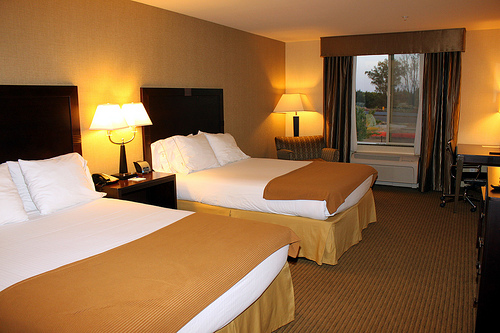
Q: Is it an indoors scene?
A: Yes, it is indoors.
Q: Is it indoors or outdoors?
A: It is indoors.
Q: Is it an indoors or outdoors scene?
A: It is indoors.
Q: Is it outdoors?
A: No, it is indoors.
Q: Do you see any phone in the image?
A: Yes, there is a phone.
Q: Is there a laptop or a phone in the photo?
A: Yes, there is a phone.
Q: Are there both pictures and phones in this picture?
A: No, there is a phone but no pictures.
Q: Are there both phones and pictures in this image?
A: No, there is a phone but no pictures.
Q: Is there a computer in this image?
A: No, there are no computers.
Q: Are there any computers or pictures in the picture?
A: No, there are no computers or pictures.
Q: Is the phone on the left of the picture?
A: Yes, the phone is on the left of the image.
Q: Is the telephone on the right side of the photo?
A: No, the telephone is on the left of the image.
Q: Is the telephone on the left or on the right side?
A: The telephone is on the left of the image.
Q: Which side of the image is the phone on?
A: The phone is on the left of the image.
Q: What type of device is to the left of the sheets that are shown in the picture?
A: The device is a phone.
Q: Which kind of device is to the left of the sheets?
A: The device is a phone.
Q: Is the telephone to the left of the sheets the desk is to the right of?
A: Yes, the telephone is to the left of the sheets.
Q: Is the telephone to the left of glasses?
A: No, the telephone is to the left of the sheets.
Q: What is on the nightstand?
A: The phone is on the nightstand.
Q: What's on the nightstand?
A: The phone is on the nightstand.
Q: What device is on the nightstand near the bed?
A: The device is a phone.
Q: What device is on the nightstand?
A: The device is a phone.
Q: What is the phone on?
A: The phone is on the nightstand.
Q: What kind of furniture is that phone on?
A: The phone is on the nightstand.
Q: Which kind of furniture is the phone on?
A: The phone is on the nightstand.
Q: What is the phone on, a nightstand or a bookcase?
A: The phone is on a nightstand.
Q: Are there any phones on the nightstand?
A: Yes, there is a phone on the nightstand.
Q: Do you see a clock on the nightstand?
A: No, there is a phone on the nightstand.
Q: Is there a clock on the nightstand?
A: No, there is a phone on the nightstand.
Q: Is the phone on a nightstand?
A: Yes, the phone is on a nightstand.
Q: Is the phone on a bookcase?
A: No, the phone is on a nightstand.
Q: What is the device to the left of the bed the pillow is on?
A: The device is a phone.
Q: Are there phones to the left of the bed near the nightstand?
A: Yes, there is a phone to the left of the bed.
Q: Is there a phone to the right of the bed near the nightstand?
A: No, the phone is to the left of the bed.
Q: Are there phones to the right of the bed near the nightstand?
A: No, the phone is to the left of the bed.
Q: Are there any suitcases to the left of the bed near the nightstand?
A: No, there is a phone to the left of the bed.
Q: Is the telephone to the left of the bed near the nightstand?
A: Yes, the telephone is to the left of the bed.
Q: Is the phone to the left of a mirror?
A: No, the phone is to the left of the bed.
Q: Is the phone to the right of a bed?
A: No, the phone is to the left of a bed.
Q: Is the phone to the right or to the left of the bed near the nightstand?
A: The phone is to the left of the bed.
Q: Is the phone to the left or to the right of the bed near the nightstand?
A: The phone is to the left of the bed.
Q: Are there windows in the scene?
A: Yes, there is a window.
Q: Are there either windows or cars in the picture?
A: Yes, there is a window.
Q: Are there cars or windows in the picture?
A: Yes, there is a window.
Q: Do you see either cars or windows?
A: Yes, there is a window.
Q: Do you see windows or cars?
A: Yes, there is a window.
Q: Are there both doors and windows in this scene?
A: No, there is a window but no doors.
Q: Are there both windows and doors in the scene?
A: No, there is a window but no doors.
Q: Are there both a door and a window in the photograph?
A: No, there is a window but no doors.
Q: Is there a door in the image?
A: No, there are no doors.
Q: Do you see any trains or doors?
A: No, there are no doors or trains.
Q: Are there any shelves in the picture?
A: No, there are no shelves.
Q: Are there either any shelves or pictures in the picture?
A: No, there are no shelves or pictures.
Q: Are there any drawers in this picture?
A: No, there are no drawers.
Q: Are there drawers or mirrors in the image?
A: No, there are no drawers or mirrors.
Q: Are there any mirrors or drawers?
A: No, there are no drawers or mirrors.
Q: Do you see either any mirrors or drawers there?
A: No, there are no drawers or mirrors.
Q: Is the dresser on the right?
A: Yes, the dresser is on the right of the image.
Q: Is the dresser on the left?
A: No, the dresser is on the right of the image.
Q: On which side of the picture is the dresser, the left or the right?
A: The dresser is on the right of the image.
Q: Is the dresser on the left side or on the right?
A: The dresser is on the right of the image.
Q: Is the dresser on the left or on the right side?
A: The dresser is on the right of the image.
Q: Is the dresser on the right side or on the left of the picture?
A: The dresser is on the right of the image.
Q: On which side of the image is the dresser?
A: The dresser is on the right of the image.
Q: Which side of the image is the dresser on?
A: The dresser is on the right of the image.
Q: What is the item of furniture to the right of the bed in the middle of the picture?
A: The piece of furniture is a dresser.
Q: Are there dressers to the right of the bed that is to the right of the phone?
A: Yes, there is a dresser to the right of the bed.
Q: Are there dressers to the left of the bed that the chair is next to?
A: No, the dresser is to the right of the bed.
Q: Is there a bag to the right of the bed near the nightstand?
A: No, there is a dresser to the right of the bed.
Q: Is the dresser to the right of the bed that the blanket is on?
A: Yes, the dresser is to the right of the bed.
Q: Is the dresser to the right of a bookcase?
A: No, the dresser is to the right of the bed.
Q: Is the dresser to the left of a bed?
A: No, the dresser is to the right of a bed.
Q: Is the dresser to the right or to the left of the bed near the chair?
A: The dresser is to the right of the bed.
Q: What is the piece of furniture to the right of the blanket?
A: The piece of furniture is a dresser.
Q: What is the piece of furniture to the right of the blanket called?
A: The piece of furniture is a dresser.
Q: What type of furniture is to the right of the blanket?
A: The piece of furniture is a dresser.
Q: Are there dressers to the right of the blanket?
A: Yes, there is a dresser to the right of the blanket.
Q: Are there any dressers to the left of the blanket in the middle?
A: No, the dresser is to the right of the blanket.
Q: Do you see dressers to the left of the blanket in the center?
A: No, the dresser is to the right of the blanket.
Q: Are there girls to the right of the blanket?
A: No, there is a dresser to the right of the blanket.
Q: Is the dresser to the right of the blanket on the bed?
A: Yes, the dresser is to the right of the blanket.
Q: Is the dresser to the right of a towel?
A: No, the dresser is to the right of the blanket.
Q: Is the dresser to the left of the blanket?
A: No, the dresser is to the right of the blanket.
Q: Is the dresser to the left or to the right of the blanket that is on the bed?
A: The dresser is to the right of the blanket.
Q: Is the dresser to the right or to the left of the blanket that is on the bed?
A: The dresser is to the right of the blanket.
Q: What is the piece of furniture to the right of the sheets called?
A: The piece of furniture is a dresser.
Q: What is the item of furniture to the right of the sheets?
A: The piece of furniture is a dresser.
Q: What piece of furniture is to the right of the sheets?
A: The piece of furniture is a dresser.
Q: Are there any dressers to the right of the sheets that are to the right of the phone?
A: Yes, there is a dresser to the right of the sheets.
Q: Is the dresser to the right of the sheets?
A: Yes, the dresser is to the right of the sheets.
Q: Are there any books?
A: No, there are no books.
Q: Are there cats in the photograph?
A: No, there are no cats.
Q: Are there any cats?
A: No, there are no cats.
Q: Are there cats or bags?
A: No, there are no cats or bags.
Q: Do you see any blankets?
A: Yes, there is a blanket.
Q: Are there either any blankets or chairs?
A: Yes, there is a blanket.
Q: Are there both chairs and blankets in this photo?
A: Yes, there are both a blanket and a chair.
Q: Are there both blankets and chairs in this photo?
A: Yes, there are both a blanket and a chair.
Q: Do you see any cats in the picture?
A: No, there are no cats.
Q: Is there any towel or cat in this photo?
A: No, there are no cats or towels.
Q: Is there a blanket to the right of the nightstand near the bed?
A: Yes, there is a blanket to the right of the nightstand.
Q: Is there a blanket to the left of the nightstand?
A: No, the blanket is to the right of the nightstand.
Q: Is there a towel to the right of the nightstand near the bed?
A: No, there is a blanket to the right of the nightstand.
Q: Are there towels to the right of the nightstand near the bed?
A: No, there is a blanket to the right of the nightstand.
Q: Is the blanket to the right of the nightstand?
A: Yes, the blanket is to the right of the nightstand.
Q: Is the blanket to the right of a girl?
A: No, the blanket is to the right of the nightstand.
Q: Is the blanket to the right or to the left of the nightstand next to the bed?
A: The blanket is to the right of the nightstand.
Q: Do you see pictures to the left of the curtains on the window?
A: No, there is a blanket to the left of the curtains.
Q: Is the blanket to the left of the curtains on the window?
A: Yes, the blanket is to the left of the curtains.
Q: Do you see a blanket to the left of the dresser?
A: Yes, there is a blanket to the left of the dresser.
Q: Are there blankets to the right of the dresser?
A: No, the blanket is to the left of the dresser.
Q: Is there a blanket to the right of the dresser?
A: No, the blanket is to the left of the dresser.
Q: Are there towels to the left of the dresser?
A: No, there is a blanket to the left of the dresser.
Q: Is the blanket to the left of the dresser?
A: Yes, the blanket is to the left of the dresser.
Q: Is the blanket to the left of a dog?
A: No, the blanket is to the left of the dresser.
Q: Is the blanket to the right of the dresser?
A: No, the blanket is to the left of the dresser.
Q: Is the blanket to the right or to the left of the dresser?
A: The blanket is to the left of the dresser.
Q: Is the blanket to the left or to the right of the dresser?
A: The blanket is to the left of the dresser.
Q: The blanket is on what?
A: The blanket is on the bed.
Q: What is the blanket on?
A: The blanket is on the bed.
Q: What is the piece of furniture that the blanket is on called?
A: The piece of furniture is a bed.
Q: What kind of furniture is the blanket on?
A: The blanket is on the bed.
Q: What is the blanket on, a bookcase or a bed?
A: The blanket is on a bed.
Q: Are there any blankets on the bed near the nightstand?
A: Yes, there is a blanket on the bed.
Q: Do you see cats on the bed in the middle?
A: No, there is a blanket on the bed.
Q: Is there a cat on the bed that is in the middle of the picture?
A: No, there is a blanket on the bed.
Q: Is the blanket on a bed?
A: Yes, the blanket is on a bed.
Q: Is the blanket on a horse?
A: No, the blanket is on a bed.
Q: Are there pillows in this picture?
A: Yes, there are pillows.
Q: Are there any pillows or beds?
A: Yes, there are pillows.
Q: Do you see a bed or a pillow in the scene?
A: Yes, there are pillows.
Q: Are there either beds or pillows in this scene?
A: Yes, there are pillows.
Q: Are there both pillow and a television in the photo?
A: No, there are pillows but no televisions.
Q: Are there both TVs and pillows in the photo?
A: No, there are pillows but no televisions.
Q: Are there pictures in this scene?
A: No, there are no pictures.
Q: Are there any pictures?
A: No, there are no pictures.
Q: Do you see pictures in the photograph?
A: No, there are no pictures.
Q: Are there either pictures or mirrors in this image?
A: No, there are no pictures or mirrors.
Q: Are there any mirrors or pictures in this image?
A: No, there are no pictures or mirrors.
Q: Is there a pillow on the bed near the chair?
A: Yes, there are pillows on the bed.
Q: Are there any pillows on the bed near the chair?
A: Yes, there are pillows on the bed.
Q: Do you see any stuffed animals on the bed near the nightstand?
A: No, there are pillows on the bed.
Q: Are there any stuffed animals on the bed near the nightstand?
A: No, there are pillows on the bed.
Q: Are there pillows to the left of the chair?
A: Yes, there are pillows to the left of the chair.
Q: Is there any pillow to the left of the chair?
A: Yes, there are pillows to the left of the chair.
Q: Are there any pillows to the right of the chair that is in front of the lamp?
A: No, the pillows are to the left of the chair.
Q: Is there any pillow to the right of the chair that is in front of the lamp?
A: No, the pillows are to the left of the chair.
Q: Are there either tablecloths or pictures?
A: No, there are no pictures or tablecloths.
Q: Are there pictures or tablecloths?
A: No, there are no pictures or tablecloths.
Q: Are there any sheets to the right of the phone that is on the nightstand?
A: Yes, there are sheets to the right of the phone.